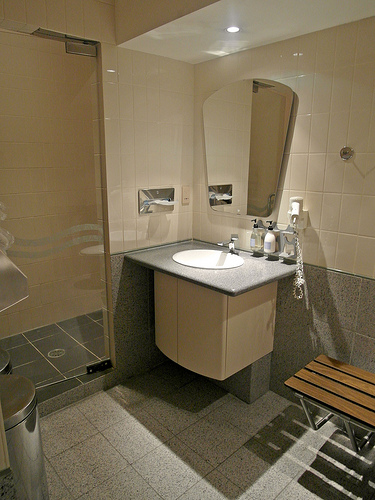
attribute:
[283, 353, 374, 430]
bench — wooden, brown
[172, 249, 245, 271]
sink — small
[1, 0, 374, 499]
bathroom — lit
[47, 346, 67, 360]
drain — circular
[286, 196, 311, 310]
hairdryer — white, mounted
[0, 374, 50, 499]
garbage can — silver, shiny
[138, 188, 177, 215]
paper tower dispense — silver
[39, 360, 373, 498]
tile — grey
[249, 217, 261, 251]
soap dispenser — mounted